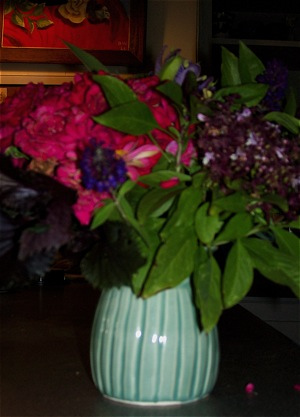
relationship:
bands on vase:
[174, 292, 199, 400] [90, 277, 228, 416]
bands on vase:
[132, 295, 163, 409] [90, 277, 228, 416]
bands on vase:
[100, 288, 114, 397] [90, 277, 228, 416]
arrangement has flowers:
[4, 53, 292, 395] [208, 105, 291, 201]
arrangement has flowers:
[4, 53, 292, 395] [259, 60, 288, 103]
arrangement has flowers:
[4, 53, 292, 395] [85, 144, 121, 185]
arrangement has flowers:
[4, 53, 292, 395] [11, 77, 171, 191]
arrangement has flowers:
[4, 53, 292, 395] [11, 70, 292, 215]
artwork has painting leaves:
[0, 1, 147, 77] [11, 17, 55, 31]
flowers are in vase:
[3, 40, 292, 304] [87, 282, 221, 405]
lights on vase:
[132, 322, 164, 350] [87, 282, 221, 405]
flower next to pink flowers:
[79, 145, 127, 190] [0, 74, 182, 224]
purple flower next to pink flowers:
[200, 94, 299, 212] [0, 74, 182, 224]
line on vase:
[200, 332, 211, 395] [91, 273, 219, 409]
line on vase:
[187, 290, 209, 400] [91, 273, 219, 409]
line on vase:
[118, 290, 134, 399] [91, 273, 219, 409]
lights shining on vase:
[132, 322, 164, 350] [91, 273, 219, 409]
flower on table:
[3, 82, 199, 188] [0, 291, 287, 415]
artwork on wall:
[0, 1, 147, 77] [153, 3, 193, 69]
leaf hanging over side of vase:
[191, 246, 225, 328] [91, 273, 219, 409]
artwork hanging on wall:
[1, 1, 147, 77] [147, 2, 195, 88]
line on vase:
[168, 290, 187, 405] [87, 282, 221, 405]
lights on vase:
[132, 322, 164, 350] [91, 273, 219, 409]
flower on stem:
[78, 151, 127, 190] [111, 187, 145, 255]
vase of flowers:
[91, 266, 215, 415] [65, 144, 129, 188]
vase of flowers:
[91, 266, 215, 415] [179, 80, 292, 190]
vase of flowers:
[91, 266, 215, 415] [10, 63, 154, 226]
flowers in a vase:
[3, 40, 292, 304] [91, 273, 219, 409]